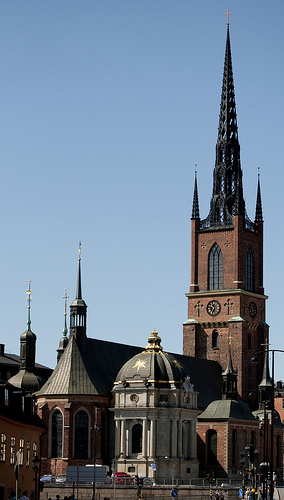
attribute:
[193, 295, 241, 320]
crosses — two big   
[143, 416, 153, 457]
columns — white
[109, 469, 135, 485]
car — red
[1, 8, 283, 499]
building — red, tiled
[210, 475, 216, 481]
traffic light — green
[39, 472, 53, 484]
car — blue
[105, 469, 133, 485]
car — red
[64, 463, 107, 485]
sign — silver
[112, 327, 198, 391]
dome — black, gold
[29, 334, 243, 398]
roof — black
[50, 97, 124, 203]
sky — clear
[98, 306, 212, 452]
roof — dome shaped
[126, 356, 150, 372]
star — gold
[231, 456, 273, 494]
person — standing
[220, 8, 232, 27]
cross — gold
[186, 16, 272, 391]
tower — tall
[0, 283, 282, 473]
building — big